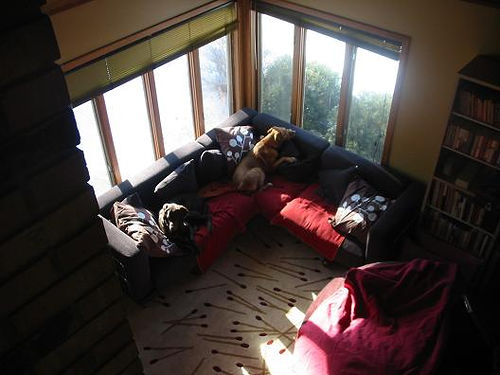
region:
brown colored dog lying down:
[226, 120, 301, 197]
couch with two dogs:
[93, 103, 412, 283]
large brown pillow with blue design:
[325, 170, 400, 241]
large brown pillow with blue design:
[212, 124, 254, 165]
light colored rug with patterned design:
[162, 277, 294, 367]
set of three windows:
[246, 1, 391, 133]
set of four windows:
[75, 32, 232, 164]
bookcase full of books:
[439, 67, 497, 264]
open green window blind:
[64, 3, 240, 100]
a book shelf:
[420, 68, 499, 245]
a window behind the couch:
[261, 20, 401, 153]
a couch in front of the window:
[99, 110, 404, 271]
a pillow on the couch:
[331, 175, 386, 240]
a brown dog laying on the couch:
[223, 121, 289, 184]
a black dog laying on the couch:
[151, 203, 206, 251]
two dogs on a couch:
[117, 132, 407, 262]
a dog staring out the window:
[236, 102, 326, 177]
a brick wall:
[1, 25, 109, 355]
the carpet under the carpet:
[146, 287, 296, 373]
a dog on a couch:
[214, 115, 321, 215]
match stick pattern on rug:
[152, 257, 312, 373]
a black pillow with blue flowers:
[322, 171, 414, 250]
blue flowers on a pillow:
[202, 116, 268, 171]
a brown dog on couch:
[205, 102, 336, 223]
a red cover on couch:
[179, 168, 355, 273]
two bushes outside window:
[245, 51, 395, 162]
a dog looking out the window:
[210, 100, 349, 230]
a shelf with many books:
[403, 63, 495, 294]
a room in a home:
[41, 32, 476, 349]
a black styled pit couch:
[102, 107, 414, 289]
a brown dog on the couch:
[232, 112, 311, 195]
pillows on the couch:
[99, 181, 199, 272]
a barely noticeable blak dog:
[148, 191, 227, 248]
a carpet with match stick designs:
[173, 257, 297, 353]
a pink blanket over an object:
[283, 232, 455, 358]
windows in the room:
[56, 13, 395, 191]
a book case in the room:
[432, 52, 497, 262]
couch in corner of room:
[111, 120, 402, 257]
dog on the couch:
[218, 123, 296, 185]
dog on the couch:
[148, 192, 241, 254]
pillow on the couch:
[327, 171, 387, 244]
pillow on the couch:
[203, 125, 259, 161]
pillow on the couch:
[106, 205, 172, 253]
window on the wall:
[253, 19, 384, 145]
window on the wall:
[69, 78, 232, 163]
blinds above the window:
[60, 18, 242, 70]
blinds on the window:
[263, 4, 407, 66]